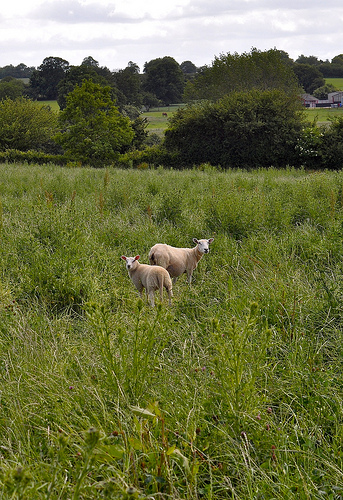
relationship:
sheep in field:
[106, 230, 229, 306] [0, 161, 341, 498]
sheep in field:
[148, 238, 213, 287] [0, 161, 341, 498]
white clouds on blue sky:
[100, 11, 151, 43] [9, 0, 326, 41]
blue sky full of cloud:
[0, 0, 342, 41] [29, 0, 146, 26]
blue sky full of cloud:
[0, 0, 342, 41] [179, 14, 302, 44]